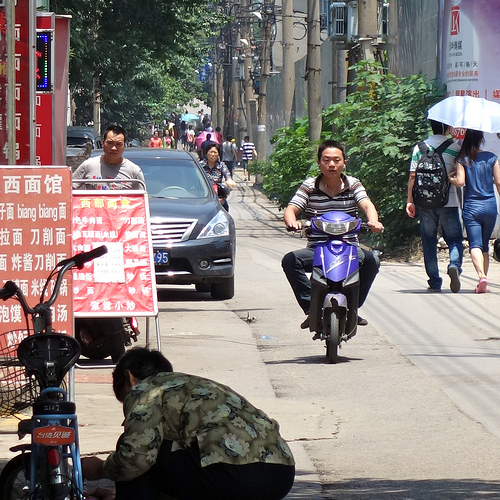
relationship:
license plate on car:
[153, 251, 167, 266] [119, 141, 238, 298]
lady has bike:
[97, 347, 301, 498] [0, 243, 109, 498]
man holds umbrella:
[407, 116, 467, 292] [430, 82, 495, 159]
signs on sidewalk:
[1, 158, 161, 371] [22, 128, 239, 415]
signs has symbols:
[1, 158, 75, 371] [0, 173, 67, 332]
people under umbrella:
[401, 112, 498, 302] [423, 91, 499, 133]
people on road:
[401, 112, 498, 302] [161, 162, 498, 495]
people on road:
[139, 98, 269, 208] [161, 162, 498, 495]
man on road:
[275, 137, 388, 332] [161, 162, 498, 495]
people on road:
[61, 125, 146, 205] [161, 162, 498, 495]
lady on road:
[97, 347, 301, 498] [161, 162, 498, 495]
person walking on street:
[448, 128, 499, 292] [4, 160, 498, 498]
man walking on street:
[407, 116, 467, 292] [4, 160, 498, 498]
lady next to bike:
[97, 347, 301, 498] [0, 243, 109, 498]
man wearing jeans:
[407, 116, 467, 292] [417, 205, 464, 290]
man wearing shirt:
[275, 137, 388, 332] [284, 170, 373, 244]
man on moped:
[275, 137, 388, 332] [283, 209, 388, 365]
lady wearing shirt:
[97, 347, 301, 498] [108, 364, 296, 474]